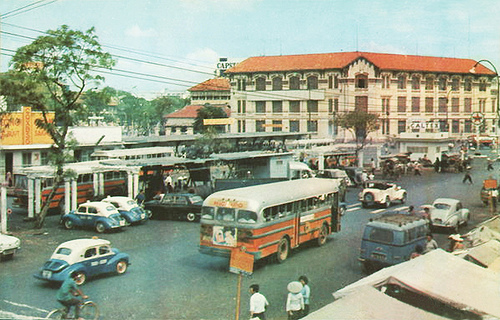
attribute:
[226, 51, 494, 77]
roof — orange 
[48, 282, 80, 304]
shirt — green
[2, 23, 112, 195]
tree — tall, green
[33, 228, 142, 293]
car — Blue , white 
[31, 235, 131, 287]
car — white , Blue 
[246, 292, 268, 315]
shirt — white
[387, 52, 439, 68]
roof — red 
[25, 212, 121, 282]
car — Blue , white 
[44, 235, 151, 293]
car — white , Blue 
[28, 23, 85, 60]
leaves — green 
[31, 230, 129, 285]
car — blue, white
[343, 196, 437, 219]
lines — white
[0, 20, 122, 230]
tree — tall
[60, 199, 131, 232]
car — parked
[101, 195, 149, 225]
car — parked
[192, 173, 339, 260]
bus — orange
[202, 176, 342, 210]
top — white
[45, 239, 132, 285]
car — blue, white, passing